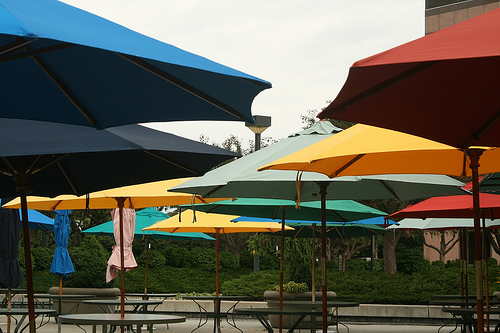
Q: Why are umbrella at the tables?
A: To protect people from the sun.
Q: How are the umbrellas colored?
A: All different colors.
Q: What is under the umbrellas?
A: Tables.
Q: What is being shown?
A: Umbrellas.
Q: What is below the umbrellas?
A: Tables.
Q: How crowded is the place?
A: Not at all.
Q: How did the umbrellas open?
A: Someone opened them.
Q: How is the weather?
A: Sunny.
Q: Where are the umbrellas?
A: Above tables.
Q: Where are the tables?
A: Below the umbrellas.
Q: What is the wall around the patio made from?
A: Cement.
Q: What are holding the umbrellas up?
A: Poles.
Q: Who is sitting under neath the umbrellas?
A: No one is sitting under neath the umbrellas.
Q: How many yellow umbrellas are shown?
A: 3.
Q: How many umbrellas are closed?
A: 2.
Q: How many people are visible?
A: 0.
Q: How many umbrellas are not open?
A: 2.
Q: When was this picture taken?
A: Daytime.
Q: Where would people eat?
A: Tables.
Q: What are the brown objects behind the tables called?
A: Planters.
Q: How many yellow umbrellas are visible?
A: 3.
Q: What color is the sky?
A: Gray.